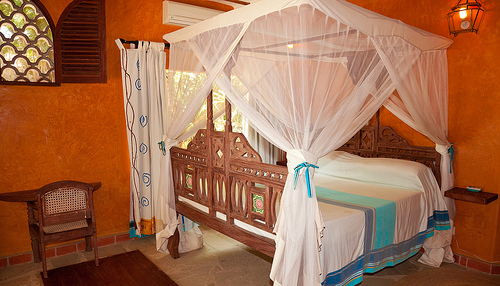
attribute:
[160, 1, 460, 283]
drapes — bed, white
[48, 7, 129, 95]
cover — wooden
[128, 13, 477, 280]
bed — brown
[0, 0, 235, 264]
wall — orange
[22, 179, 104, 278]
cair — brown